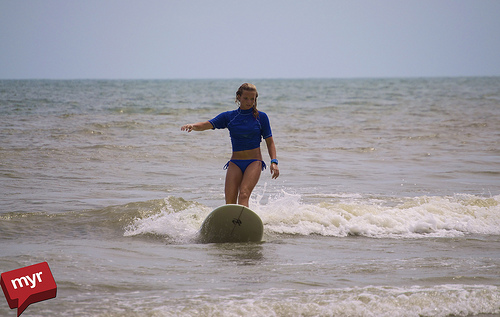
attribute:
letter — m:
[8, 276, 31, 291]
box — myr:
[1, 261, 58, 316]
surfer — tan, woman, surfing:
[180, 83, 281, 207]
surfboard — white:
[198, 202, 265, 244]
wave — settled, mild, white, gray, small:
[1, 194, 498, 244]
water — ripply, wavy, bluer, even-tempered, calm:
[1, 78, 500, 315]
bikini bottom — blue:
[220, 158, 267, 176]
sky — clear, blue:
[1, 1, 499, 79]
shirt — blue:
[208, 107, 274, 153]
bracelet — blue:
[270, 157, 280, 166]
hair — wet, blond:
[235, 82, 261, 124]